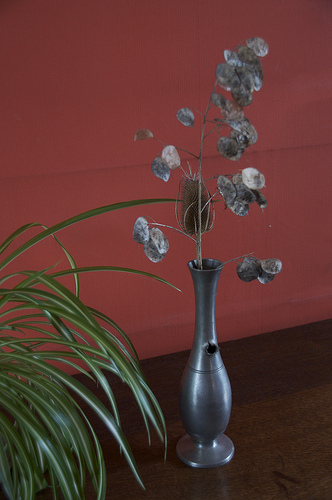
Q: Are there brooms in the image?
A: No, there are no brooms.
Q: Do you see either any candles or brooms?
A: No, there are no brooms or candles.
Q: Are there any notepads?
A: No, there are no notepads.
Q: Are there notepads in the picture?
A: No, there are no notepads.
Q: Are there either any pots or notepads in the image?
A: No, there are no notepads or pots.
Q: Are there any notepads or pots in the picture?
A: No, there are no notepads or pots.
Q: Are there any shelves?
A: No, there are no shelves.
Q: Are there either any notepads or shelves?
A: No, there are no shelves or notepads.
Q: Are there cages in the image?
A: No, there are no cages.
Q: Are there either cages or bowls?
A: No, there are no cages or bowls.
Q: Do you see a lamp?
A: No, there are no lamps.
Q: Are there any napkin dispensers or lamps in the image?
A: No, there are no lamps or napkin dispensers.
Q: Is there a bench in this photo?
A: No, there are no benches.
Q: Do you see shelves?
A: No, there are no shelves.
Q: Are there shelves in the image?
A: No, there are no shelves.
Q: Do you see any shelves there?
A: No, there are no shelves.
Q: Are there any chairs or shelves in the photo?
A: No, there are no shelves or chairs.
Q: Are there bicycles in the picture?
A: No, there are no bicycles.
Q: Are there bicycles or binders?
A: No, there are no bicycles or binders.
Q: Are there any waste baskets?
A: No, there are no waste baskets.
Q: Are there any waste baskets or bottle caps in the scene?
A: No, there are no waste baskets or bottle caps.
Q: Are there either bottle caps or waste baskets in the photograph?
A: No, there are no waste baskets or bottle caps.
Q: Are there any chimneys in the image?
A: No, there are no chimneys.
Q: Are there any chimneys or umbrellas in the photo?
A: No, there are no chimneys or umbrellas.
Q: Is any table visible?
A: Yes, there is a table.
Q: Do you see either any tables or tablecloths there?
A: Yes, there is a table.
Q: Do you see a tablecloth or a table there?
A: Yes, there is a table.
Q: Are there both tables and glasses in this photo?
A: No, there is a table but no glasses.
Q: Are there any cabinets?
A: No, there are no cabinets.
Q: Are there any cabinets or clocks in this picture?
A: No, there are no cabinets or clocks.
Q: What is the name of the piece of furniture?
A: The piece of furniture is a table.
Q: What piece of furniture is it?
A: The piece of furniture is a table.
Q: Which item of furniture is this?
A: This is a table.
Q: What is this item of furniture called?
A: This is a table.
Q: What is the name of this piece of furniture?
A: This is a table.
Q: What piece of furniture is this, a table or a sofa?
A: This is a table.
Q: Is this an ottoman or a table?
A: This is a table.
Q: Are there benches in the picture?
A: No, there are no benches.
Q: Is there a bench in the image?
A: No, there are no benches.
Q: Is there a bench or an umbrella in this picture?
A: No, there are no benches or umbrellas.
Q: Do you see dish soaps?
A: No, there are no dish soaps.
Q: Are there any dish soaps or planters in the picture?
A: No, there are no dish soaps or planters.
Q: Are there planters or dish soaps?
A: No, there are no dish soaps or planters.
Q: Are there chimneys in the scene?
A: No, there are no chimneys.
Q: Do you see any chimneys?
A: No, there are no chimneys.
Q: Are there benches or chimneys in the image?
A: No, there are no chimneys or benches.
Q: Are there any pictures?
A: No, there are no pictures.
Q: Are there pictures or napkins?
A: No, there are no pictures or napkins.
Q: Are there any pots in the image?
A: No, there are no pots.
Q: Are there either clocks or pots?
A: No, there are no pots or clocks.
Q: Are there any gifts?
A: No, there are no gifts.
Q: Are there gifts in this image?
A: No, there are no gifts.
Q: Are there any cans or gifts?
A: No, there are no gifts or cans.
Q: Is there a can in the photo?
A: No, there are no cans.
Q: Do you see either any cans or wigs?
A: No, there are no cans or wigs.